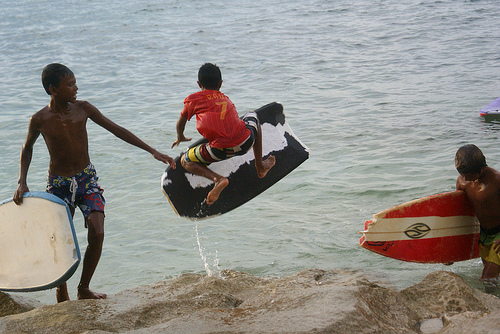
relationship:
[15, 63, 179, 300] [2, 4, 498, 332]
kids are at beach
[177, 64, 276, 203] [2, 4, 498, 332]
kids are at beach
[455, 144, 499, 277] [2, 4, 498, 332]
kids are at beach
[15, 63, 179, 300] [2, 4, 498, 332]
kids are playing at beach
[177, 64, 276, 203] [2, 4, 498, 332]
kids are playing at beach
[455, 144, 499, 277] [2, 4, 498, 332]
kids are playing at beach